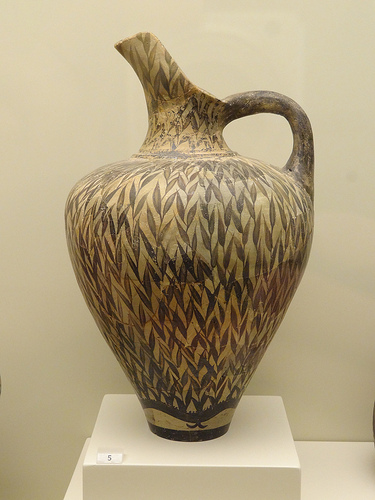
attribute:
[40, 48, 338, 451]
artifact — here, brown, yellow, pitcher, designed, patterned, fat, bronze color, tall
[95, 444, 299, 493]
display stand — white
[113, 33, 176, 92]
spout — for pouring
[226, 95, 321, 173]
handle — short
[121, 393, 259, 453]
base — brown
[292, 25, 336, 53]
wall — white, blank